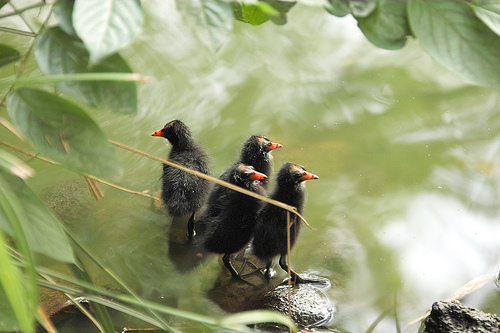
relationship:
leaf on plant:
[29, 23, 137, 114] [2, 0, 493, 330]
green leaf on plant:
[0, 173, 80, 271] [2, 0, 493, 330]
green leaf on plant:
[70, 0, 144, 69] [2, 0, 493, 330]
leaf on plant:
[357, 0, 412, 51] [2, 0, 493, 330]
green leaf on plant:
[406, 0, 500, 88] [69, 0, 499, 87]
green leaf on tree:
[5, 83, 124, 188] [0, 0, 498, 330]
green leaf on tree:
[0, 83, 125, 175] [338, 76, 483, 227]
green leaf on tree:
[175, 1, 229, 55] [0, 0, 498, 330]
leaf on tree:
[326, 0, 373, 17] [0, 0, 498, 175]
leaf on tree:
[357, 0, 412, 51] [0, 0, 498, 330]